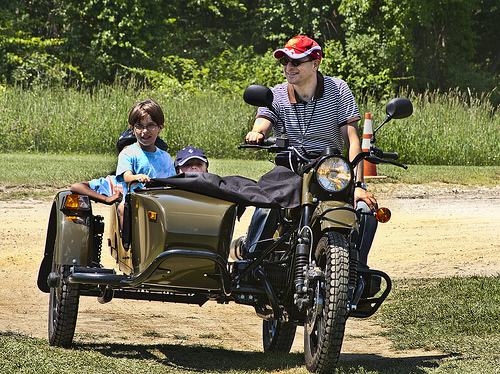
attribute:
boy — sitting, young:
[113, 94, 180, 195]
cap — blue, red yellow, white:
[169, 140, 215, 171]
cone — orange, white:
[359, 109, 381, 179]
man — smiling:
[243, 33, 386, 206]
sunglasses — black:
[274, 54, 319, 68]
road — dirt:
[4, 185, 496, 332]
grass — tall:
[0, 146, 495, 197]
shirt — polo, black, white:
[248, 72, 367, 163]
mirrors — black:
[237, 79, 416, 130]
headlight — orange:
[307, 150, 362, 195]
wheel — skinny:
[38, 210, 89, 350]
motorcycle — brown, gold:
[242, 82, 417, 373]